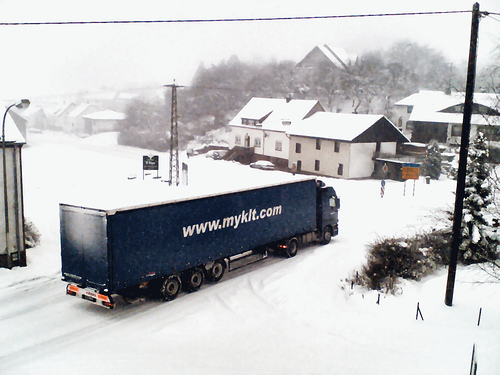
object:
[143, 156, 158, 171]
sign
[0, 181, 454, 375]
road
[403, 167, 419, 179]
sign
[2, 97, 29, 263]
street light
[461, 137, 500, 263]
pine tree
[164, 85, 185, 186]
telephone post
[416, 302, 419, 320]
sign posts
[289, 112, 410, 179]
building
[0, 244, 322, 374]
snow tracks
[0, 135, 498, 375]
ground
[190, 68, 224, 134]
trees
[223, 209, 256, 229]
words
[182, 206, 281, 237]
website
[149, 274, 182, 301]
wheels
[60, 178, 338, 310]
truck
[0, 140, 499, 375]
snow